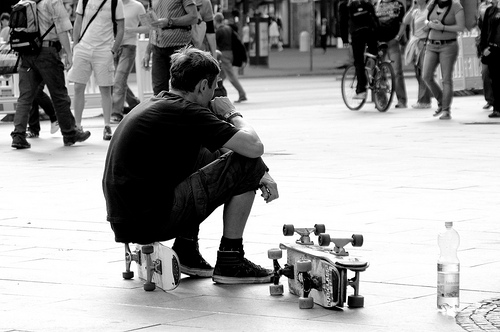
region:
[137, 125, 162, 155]
man wearing black shirt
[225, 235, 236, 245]
man wearing black socks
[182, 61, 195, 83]
man has black hair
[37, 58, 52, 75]
man wearing black pants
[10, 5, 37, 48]
bookbag on mans back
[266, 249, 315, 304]
bottom wheels on board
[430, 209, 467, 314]
bottle of water on street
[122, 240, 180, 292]
skateboard on the ground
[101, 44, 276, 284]
guy sitting on a skateboard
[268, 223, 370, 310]
group of three skateboards on the ground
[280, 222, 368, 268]
one skateboard laying on two skateboards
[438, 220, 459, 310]
bottle of water on the ground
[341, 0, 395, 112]
person riding a bycicle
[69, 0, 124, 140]
person in white shorts with his hands in his pockets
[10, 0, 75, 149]
person walking with a backpack on his back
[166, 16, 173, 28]
watch on a person's wrist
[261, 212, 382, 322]
three skateboards piled up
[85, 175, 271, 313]
he is sitting on his skateboard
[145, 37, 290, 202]
this guy's arm is folded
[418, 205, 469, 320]
a bottle of water in the shot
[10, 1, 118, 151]
people in the background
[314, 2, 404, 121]
a bicycle rider in the shot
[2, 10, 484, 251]
this photo is black and white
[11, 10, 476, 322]
a black and white picture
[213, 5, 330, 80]
a building in the background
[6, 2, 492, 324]
The picture is in black and white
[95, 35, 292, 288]
The man is sitting on a skateboard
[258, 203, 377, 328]
Three skateboards piled up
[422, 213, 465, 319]
A bottle of water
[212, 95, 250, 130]
The man has a watch on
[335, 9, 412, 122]
A person riding a bike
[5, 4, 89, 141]
A person wearing a backpack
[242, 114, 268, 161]
His right elbow is on his right knee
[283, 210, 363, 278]
The top skateboard is upside down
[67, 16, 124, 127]
This person is wearing shorts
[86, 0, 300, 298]
this is a man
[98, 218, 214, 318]
this is a skateboard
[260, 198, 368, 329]
a set of stacked skateboards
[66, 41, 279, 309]
man sitting on a skateboard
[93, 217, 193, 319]
skateboard is flipped on side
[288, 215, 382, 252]
wheels on the skateboard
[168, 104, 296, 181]
arm on knees leg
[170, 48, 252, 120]
man touching his face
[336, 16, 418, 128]
this is a bike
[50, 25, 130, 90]
a person wearing shorts